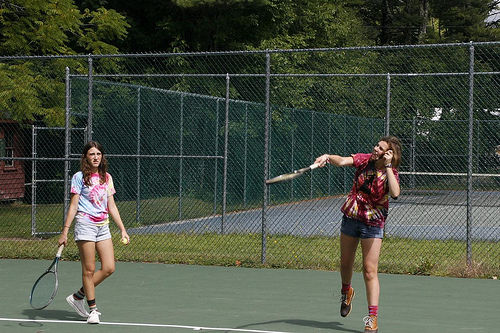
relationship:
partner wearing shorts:
[57, 139, 133, 326] [69, 214, 115, 242]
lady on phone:
[310, 134, 404, 332] [374, 147, 394, 160]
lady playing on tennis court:
[310, 134, 404, 332] [0, 39, 494, 331]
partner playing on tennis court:
[57, 139, 133, 326] [0, 39, 494, 331]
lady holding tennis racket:
[310, 134, 404, 332] [257, 162, 323, 183]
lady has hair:
[310, 134, 404, 332] [386, 135, 404, 173]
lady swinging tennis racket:
[310, 134, 404, 332] [261, 164, 320, 188]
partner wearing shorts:
[57, 139, 133, 326] [68, 212, 115, 252]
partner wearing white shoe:
[57, 139, 133, 326] [87, 307, 102, 324]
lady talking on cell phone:
[310, 134, 404, 332] [379, 147, 398, 172]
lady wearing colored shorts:
[310, 134, 404, 332] [336, 211, 387, 240]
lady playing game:
[310, 134, 404, 332] [20, 222, 473, 331]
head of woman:
[64, 141, 127, 177] [311, 132, 418, 279]